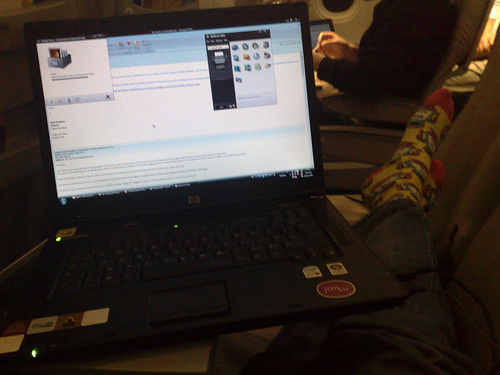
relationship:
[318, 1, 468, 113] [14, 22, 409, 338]
person using laptop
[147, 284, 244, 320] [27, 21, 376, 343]
mouse pad on laptop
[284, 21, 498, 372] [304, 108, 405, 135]
seat has arm rest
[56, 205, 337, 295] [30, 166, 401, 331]
button on keyboard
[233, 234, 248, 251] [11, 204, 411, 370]
button on keyboard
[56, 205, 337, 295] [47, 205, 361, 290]
button on keyboard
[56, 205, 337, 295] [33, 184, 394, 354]
button on keyboard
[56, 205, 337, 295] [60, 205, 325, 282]
button on keyboard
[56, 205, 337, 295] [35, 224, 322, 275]
button on keyboard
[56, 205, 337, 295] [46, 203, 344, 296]
button on keyboard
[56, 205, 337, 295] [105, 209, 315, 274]
button on keyboard